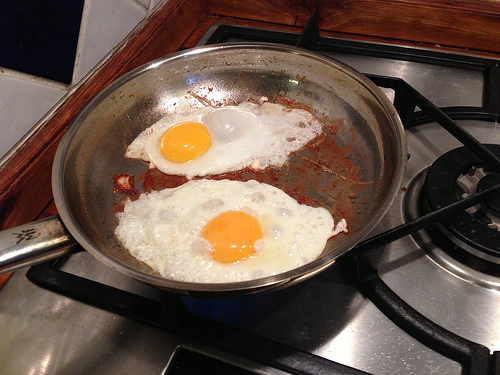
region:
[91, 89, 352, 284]
eggs cooking in pan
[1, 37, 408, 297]
metal frying pan on stove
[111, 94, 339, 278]
egg whites in bubbling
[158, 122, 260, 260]
egg yolks are orange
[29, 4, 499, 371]
stovetop black burner covers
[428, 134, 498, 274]
gas stove burner head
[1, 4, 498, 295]
wooden moulding backwash boards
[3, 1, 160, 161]
white and black tile wall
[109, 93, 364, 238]
brown overcooked pieces in pan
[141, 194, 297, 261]
tiny air bubbles in bottom egg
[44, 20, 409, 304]
round pan on stove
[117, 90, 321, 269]
eggs frying in pan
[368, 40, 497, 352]
black grate on stovetop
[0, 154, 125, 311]
handle of frying pan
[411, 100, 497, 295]
round burner on stove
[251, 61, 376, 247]
burn marks in frying pan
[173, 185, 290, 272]
yellow yoke of egg in front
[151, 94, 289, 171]
bubble on fried egg in back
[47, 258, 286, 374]
silver surface of stovetop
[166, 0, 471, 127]
wooden border of stove top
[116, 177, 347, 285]
egg frying in pan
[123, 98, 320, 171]
egg with bubble on top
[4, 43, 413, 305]
stainless steel frying pan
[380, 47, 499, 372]
gas unit on stove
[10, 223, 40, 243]
manufacturer's markings on pan handle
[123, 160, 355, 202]
browned grease in pan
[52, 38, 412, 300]
two eggs frying in pan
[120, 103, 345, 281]
two eggs sunny-side up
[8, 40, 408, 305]
frying pan with eggs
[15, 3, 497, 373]
top of gas stove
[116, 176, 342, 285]
Egg sitting in a pan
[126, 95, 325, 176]
An egg in a pan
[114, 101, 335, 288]
Two eggs in a pan, cooking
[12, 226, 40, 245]
Letters on a pan's handle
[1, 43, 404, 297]
A stainless steel pain containing eggs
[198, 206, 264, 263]
The yolk of an egg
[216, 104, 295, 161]
The bubbling white of an egg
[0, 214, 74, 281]
A handle of the pan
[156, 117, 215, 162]
A yolk of an egg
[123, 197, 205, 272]
Bubbling white of an egg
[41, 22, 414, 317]
a pan with eggs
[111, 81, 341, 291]
fried eggs on pan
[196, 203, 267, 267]
the egg yolk is orange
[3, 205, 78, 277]
the handle of pan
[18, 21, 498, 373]
burner is color black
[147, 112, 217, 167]
the yolk of egg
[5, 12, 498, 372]
top of stove is silver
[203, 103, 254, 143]
a bubble in the egg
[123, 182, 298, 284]
small bubbles on egg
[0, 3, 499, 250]
border on side the stove